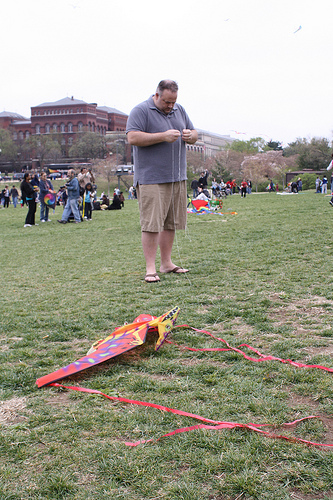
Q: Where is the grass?
A: On the ground.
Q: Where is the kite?
A: On the ground.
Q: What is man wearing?
A: Shorts.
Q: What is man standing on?
A: Grass.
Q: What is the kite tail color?
A: Red.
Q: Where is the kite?
A: The ground.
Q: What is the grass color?
A: Green.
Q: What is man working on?
A: Kite string.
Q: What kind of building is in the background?
A: A large brick building.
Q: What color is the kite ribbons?
A: Red.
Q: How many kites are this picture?
A: One.